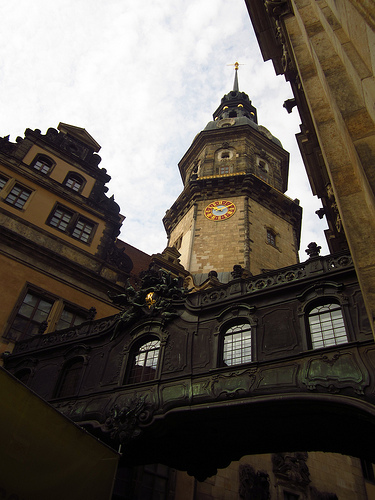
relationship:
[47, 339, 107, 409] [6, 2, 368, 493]
window on building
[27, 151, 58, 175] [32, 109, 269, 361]
window on building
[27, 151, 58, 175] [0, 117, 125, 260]
window on building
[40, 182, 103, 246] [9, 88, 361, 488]
window on building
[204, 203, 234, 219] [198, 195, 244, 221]
roman numerals are on clock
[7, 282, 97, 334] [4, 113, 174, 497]
window on a building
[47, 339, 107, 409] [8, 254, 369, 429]
window on building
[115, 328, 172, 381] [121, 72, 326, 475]
window on building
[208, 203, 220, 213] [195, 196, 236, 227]
clock hand on clock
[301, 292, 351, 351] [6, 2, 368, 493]
window on building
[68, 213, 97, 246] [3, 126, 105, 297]
window on building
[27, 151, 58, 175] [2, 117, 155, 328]
window on building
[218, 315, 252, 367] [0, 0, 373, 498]
window on bulding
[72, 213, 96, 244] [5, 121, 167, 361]
window on building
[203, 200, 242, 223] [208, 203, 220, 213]
clock has clock hand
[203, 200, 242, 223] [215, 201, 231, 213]
clock has clock hand